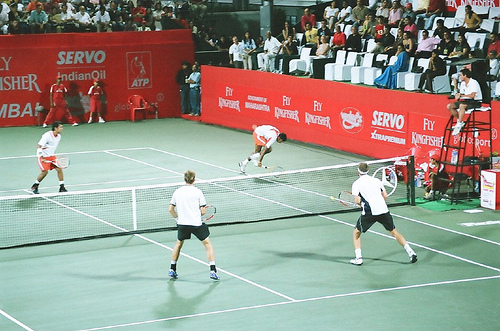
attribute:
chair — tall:
[433, 56, 493, 206]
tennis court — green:
[3, 123, 498, 329]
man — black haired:
[350, 160, 419, 264]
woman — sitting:
[363, 39, 408, 96]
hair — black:
[278, 128, 290, 141]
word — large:
[55, 46, 109, 64]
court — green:
[1, 117, 498, 328]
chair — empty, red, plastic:
[124, 81, 186, 131]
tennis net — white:
[2, 142, 412, 248]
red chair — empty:
[119, 88, 159, 124]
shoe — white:
[450, 119, 464, 136]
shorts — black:
[169, 222, 213, 246]